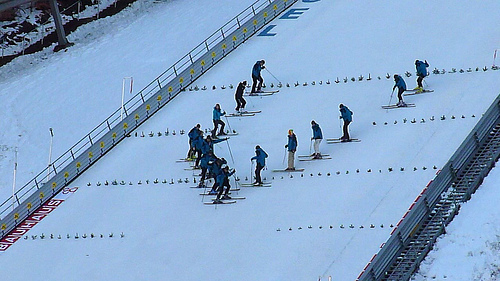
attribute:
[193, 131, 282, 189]
people — these, skiing, skating, here, seven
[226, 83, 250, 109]
man — standing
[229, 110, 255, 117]
skis — thin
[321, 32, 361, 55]
path — white, slanting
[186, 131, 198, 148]
jacket — light blue, blue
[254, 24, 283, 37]
l — large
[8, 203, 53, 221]
banner — red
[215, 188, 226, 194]
pants — white, black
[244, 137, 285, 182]
person — leaning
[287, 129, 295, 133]
hat — yellow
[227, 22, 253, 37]
signs — yellow, here, hanging